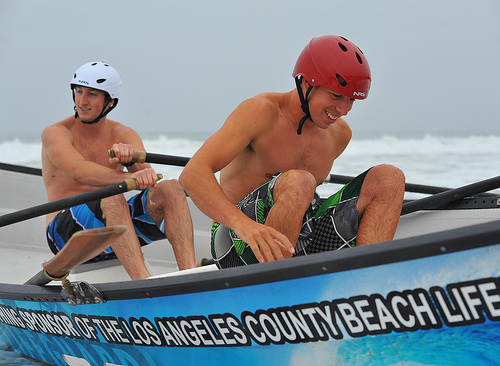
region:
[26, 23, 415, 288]
two boys rowing a boat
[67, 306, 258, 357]
white words on a boat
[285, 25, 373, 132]
red helmet on a boy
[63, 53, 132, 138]
white helmet on a boy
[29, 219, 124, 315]
extra oar sticking out from boat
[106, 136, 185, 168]
hand holding handle of oar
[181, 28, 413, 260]
bare chested boy rowing a boat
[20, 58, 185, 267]
boy in swimming suit rowing a boat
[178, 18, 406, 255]
smiling boy in swimming suit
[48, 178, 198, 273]
blue and black swim trunks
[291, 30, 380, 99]
red helmet on young man's head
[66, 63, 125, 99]
white helmet on young man's head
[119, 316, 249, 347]
words "los angeles" on boat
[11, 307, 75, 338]
word "sponsor" on boat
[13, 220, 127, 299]
oar that is not being touched at the moment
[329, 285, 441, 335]
word "beach" on boat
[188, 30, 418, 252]
young man smiling in black, green, and white shorts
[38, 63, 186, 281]
young man in back wearing black and blue shorts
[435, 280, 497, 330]
word "life" on boat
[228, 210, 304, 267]
right hand of the young man in front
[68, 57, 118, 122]
White helmet worn by boater in the back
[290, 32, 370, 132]
Red helmet of boater in the front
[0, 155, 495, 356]
Blue, white and black row boat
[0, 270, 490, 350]
Information on the side of the boat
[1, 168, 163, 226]
Row handle of paddle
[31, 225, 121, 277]
Paddle part of row boat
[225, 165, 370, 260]
Green, black and white swim trunks of front boater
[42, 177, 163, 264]
Blue, black and white swim trunks of back boater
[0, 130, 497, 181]
Waves on side of boaters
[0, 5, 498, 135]
Sky above two boaters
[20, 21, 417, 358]
two men rowing a boat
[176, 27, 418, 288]
smiling man in a boat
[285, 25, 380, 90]
red and black safety helmet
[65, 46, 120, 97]
white and black safety helmet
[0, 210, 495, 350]
blue and grey boat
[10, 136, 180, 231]
black boat oars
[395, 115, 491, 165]
ocean waves rolling in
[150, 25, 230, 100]
grey sky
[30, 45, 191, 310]
man in blue and black swim trunks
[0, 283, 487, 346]
white lettering on a boat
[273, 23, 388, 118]
man wearing a red helmet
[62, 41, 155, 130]
man wearing a white helmet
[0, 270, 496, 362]
writing on the boat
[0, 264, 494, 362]
writing is in white letters with a black boarder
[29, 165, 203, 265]
black and blue shorts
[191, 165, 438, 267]
green and black shorts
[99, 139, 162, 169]
brown handle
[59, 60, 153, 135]
boy is smiling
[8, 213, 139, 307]
wooden paddle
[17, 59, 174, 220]
boy not wearing a shirt